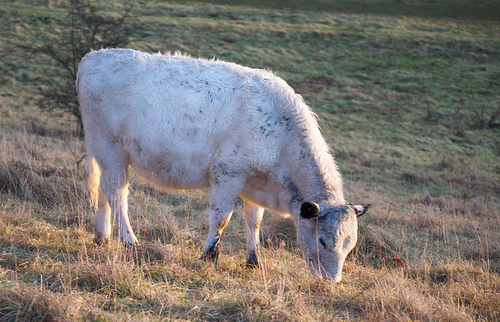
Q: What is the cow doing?
A: Eating grass.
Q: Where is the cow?
A: In a field.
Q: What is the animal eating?
A: Grass.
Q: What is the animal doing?
A: Watching.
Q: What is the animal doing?
A: Eating.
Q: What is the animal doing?
A: Standing.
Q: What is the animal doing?
A: Enjoying.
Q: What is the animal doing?
A: Standing.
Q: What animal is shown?
A: Cow.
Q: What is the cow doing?
A: Eating.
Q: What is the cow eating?
A: Grass.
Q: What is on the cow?
A: Fur.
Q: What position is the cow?
A: Head down.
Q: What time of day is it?
A: Evening.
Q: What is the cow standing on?
A: The grass.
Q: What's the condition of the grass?
A: Dry.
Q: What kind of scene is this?
A: Outdoor scene.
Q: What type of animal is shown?
A: Cow.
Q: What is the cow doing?
A: Grazing.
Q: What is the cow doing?
A: Eating.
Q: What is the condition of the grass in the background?
A: Green and brown.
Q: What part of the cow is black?
A: Front feet and ears.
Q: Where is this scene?
A: Field.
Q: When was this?
A: Daytime.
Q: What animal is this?
A: Sheep.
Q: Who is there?
A: No one.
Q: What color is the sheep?
A: White.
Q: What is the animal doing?
A: Feeding.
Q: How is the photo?
A: Clear.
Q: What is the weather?
A: Sunny.